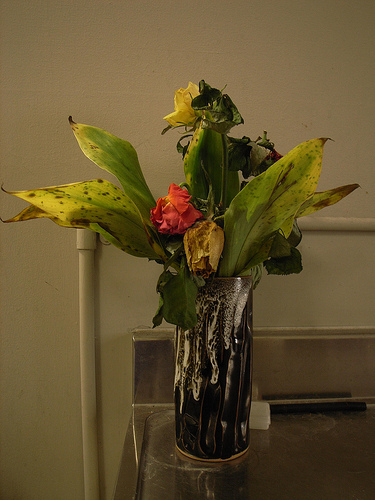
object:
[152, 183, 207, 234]
rose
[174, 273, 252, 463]
vase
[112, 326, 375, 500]
table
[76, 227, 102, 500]
pipe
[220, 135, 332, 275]
leaf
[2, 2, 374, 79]
wall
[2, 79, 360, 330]
flower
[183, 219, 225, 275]
rose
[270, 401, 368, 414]
object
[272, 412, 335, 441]
residue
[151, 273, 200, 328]
leave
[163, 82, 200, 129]
rose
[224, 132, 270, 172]
leaves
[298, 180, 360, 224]
leaves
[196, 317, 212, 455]
stripes